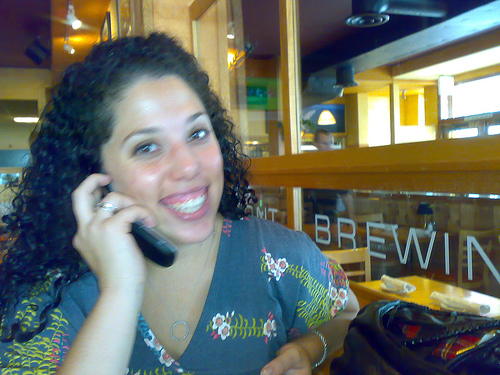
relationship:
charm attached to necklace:
[165, 316, 200, 349] [134, 264, 216, 319]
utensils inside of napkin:
[467, 299, 487, 310] [432, 286, 490, 313]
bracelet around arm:
[301, 329, 331, 365] [73, 294, 80, 299]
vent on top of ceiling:
[337, 2, 401, 24] [305, 5, 329, 50]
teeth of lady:
[172, 200, 201, 214] [6, 15, 352, 331]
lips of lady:
[167, 188, 211, 223] [6, 15, 352, 331]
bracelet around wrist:
[301, 329, 331, 365] [89, 273, 152, 305]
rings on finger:
[96, 198, 129, 222] [70, 162, 99, 213]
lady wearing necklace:
[6, 15, 352, 331] [134, 264, 216, 319]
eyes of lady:
[119, 126, 222, 149] [6, 15, 352, 331]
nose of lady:
[152, 158, 210, 187] [6, 15, 352, 331]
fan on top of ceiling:
[403, 3, 442, 23] [305, 5, 329, 50]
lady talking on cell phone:
[0, 15, 362, 375] [135, 233, 180, 263]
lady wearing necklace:
[0, 15, 362, 375] [134, 264, 216, 319]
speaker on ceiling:
[12, 35, 54, 59] [305, 5, 329, 50]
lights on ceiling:
[35, 5, 274, 62] [305, 5, 329, 50]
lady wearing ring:
[0, 15, 362, 375] [91, 202, 120, 218]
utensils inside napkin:
[467, 299, 487, 310] [432, 286, 490, 313]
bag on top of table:
[423, 294, 483, 360] [350, 291, 426, 351]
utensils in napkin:
[467, 299, 487, 310] [432, 286, 490, 313]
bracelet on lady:
[301, 329, 331, 365] [0, 15, 362, 375]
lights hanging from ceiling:
[35, 5, 274, 62] [305, 5, 329, 50]